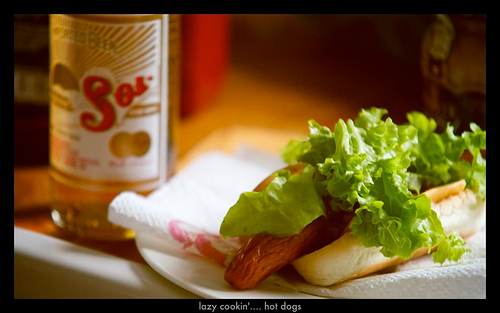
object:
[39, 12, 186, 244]
bottle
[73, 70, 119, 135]
letters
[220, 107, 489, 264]
lettuce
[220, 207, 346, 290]
hot dog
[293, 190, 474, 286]
bun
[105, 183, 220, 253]
napkin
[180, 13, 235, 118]
object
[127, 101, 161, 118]
word beer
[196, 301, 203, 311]
letters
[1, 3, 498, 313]
picture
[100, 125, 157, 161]
symbol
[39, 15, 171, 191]
label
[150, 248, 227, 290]
plate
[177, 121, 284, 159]
paper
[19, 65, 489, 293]
table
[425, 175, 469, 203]
cheese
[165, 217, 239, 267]
red designs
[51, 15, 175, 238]
liquid